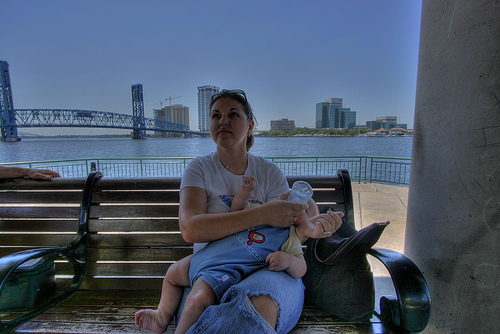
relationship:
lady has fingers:
[134, 88, 343, 334] [301, 209, 345, 238]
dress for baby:
[189, 225, 291, 300] [128, 188, 321, 332]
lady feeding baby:
[134, 88, 343, 334] [133, 176, 319, 334]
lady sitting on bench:
[134, 88, 343, 334] [7, 166, 433, 332]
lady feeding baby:
[134, 88, 343, 334] [132, 201, 321, 329]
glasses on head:
[211, 89, 248, 102] [208, 88, 254, 148]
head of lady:
[208, 88, 254, 148] [134, 88, 343, 334]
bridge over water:
[0, 60, 210, 142] [5, 134, 445, 184]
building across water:
[316, 97, 357, 129] [253, 137, 398, 159]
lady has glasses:
[134, 88, 343, 334] [211, 82, 248, 101]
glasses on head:
[211, 82, 248, 101] [202, 90, 259, 147]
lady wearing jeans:
[134, 88, 343, 334] [211, 247, 376, 322]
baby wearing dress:
[133, 176, 319, 334] [188, 215, 298, 297]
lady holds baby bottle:
[134, 88, 343, 334] [287, 179, 317, 209]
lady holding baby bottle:
[134, 88, 343, 334] [269, 159, 316, 238]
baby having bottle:
[133, 176, 319, 334] [285, 179, 315, 214]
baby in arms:
[133, 176, 319, 334] [179, 154, 318, 241]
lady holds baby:
[134, 88, 343, 334] [148, 177, 372, 304]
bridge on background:
[0, 59, 209, 139] [8, 100, 209, 125]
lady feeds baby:
[134, 88, 343, 334] [133, 176, 319, 334]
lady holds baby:
[134, 88, 343, 334] [124, 177, 342, 324]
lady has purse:
[134, 88, 343, 334] [301, 219, 391, 320]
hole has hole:
[236, 290, 285, 333] [232, 273, 294, 329]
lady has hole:
[168, 88, 308, 332] [236, 290, 285, 333]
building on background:
[313, 94, 359, 132] [12, 107, 401, 136]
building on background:
[194, 81, 214, 133] [12, 107, 401, 136]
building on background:
[365, 115, 409, 131] [12, 107, 401, 136]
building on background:
[150, 95, 191, 137] [12, 107, 401, 136]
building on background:
[264, 115, 297, 135] [12, 107, 401, 136]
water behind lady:
[2, 135, 414, 182] [168, 88, 308, 332]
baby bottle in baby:
[288, 181, 313, 204] [133, 176, 319, 334]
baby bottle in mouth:
[288, 181, 313, 204] [285, 197, 294, 203]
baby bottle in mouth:
[288, 181, 313, 204] [210, 125, 236, 139]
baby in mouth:
[133, 176, 319, 334] [212, 126, 238, 136]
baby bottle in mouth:
[288, 181, 313, 204] [216, 119, 233, 134]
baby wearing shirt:
[133, 176, 319, 334] [175, 210, 296, 289]